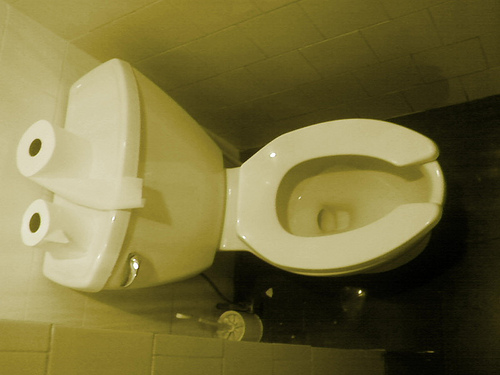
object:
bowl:
[242, 119, 445, 276]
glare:
[269, 152, 276, 157]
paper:
[16, 120, 146, 211]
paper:
[265, 288, 273, 298]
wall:
[0, 0, 499, 150]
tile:
[245, 50, 321, 94]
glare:
[357, 289, 364, 294]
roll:
[19, 199, 78, 255]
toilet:
[43, 58, 447, 293]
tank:
[41, 57, 226, 295]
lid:
[41, 57, 140, 294]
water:
[285, 162, 414, 237]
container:
[216, 309, 264, 342]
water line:
[203, 271, 243, 307]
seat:
[235, 118, 444, 273]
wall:
[0, 317, 387, 373]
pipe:
[215, 303, 231, 311]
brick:
[153, 333, 224, 359]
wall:
[0, 0, 242, 340]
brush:
[176, 309, 264, 341]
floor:
[235, 93, 499, 374]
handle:
[121, 254, 140, 287]